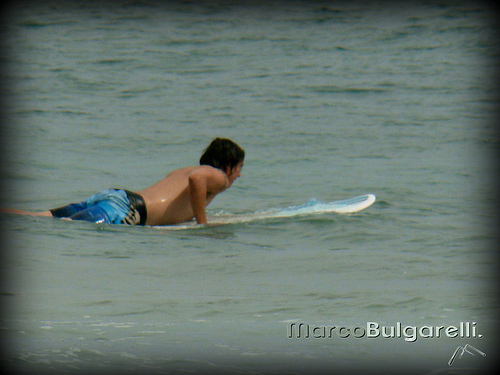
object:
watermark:
[283, 308, 486, 366]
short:
[47, 186, 147, 233]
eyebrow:
[237, 159, 251, 169]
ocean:
[333, 217, 462, 271]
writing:
[364, 320, 484, 342]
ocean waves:
[15, 13, 488, 359]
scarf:
[256, 68, 451, 150]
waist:
[120, 182, 155, 232]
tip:
[353, 182, 378, 215]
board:
[79, 163, 379, 232]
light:
[158, 195, 169, 205]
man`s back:
[134, 167, 201, 207]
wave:
[27, 25, 108, 128]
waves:
[217, 318, 367, 375]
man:
[5, 129, 250, 231]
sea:
[1, 5, 489, 368]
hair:
[198, 134, 250, 177]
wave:
[285, 77, 488, 96]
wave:
[158, 33, 290, 54]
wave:
[8, 291, 185, 329]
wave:
[158, 299, 488, 327]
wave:
[266, 68, 497, 106]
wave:
[142, 31, 317, 57]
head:
[199, 134, 249, 188]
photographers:
[279, 311, 484, 347]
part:
[362, 242, 374, 260]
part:
[92, 193, 115, 207]